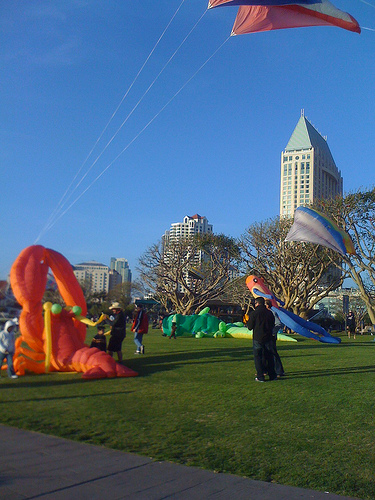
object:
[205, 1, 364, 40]
kite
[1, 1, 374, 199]
sky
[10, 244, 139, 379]
balloon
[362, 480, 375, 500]
grass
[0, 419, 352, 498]
sidewalk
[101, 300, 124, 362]
person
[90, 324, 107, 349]
person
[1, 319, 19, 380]
person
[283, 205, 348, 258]
balloon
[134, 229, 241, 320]
tree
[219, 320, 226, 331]
balloon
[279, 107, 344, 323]
building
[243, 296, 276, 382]
man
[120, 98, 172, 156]
strings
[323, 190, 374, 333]
trees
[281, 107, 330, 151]
tower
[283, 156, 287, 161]
window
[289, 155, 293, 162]
window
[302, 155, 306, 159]
window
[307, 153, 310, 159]
window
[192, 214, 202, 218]
roof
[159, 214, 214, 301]
building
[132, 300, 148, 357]
person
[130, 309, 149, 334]
coat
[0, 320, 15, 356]
jacket